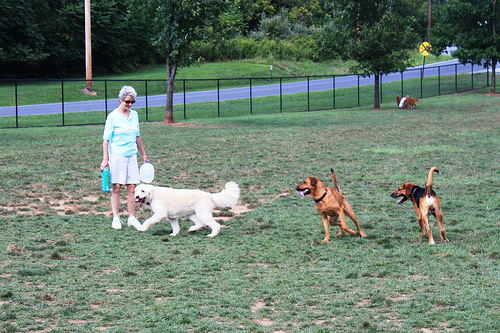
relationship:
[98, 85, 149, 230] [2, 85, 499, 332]
woman on field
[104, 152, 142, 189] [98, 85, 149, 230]
shorts on woman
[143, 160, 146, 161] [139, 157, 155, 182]
top on bottle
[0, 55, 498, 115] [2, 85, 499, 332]
road by field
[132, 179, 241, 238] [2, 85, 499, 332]
dog in field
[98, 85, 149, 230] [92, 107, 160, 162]
woman wearing shirt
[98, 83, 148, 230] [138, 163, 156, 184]
woman carrying bottle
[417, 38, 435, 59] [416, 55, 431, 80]
sign on pole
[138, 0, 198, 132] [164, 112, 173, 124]
small tree with mud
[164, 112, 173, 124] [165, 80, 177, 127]
mud on trunk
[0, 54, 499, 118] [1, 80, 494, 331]
road by dog park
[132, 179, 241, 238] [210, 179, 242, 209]
dog with tail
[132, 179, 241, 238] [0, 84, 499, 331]
dog in grass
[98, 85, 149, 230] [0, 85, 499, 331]
woman with grass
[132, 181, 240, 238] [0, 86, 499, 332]
dog in dog park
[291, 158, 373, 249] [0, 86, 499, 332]
dog in dog park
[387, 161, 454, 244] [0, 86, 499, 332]
dog in dog park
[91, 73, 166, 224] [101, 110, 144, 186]
lady in clothing